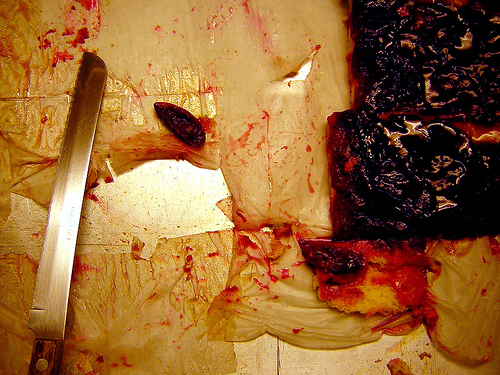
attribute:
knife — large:
[3, 48, 107, 373]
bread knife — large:
[39, 45, 110, 372]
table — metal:
[0, 1, 496, 373]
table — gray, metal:
[80, 166, 220, 246]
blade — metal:
[22, 48, 108, 338]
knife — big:
[23, 46, 108, 373]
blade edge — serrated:
[24, 48, 93, 334]